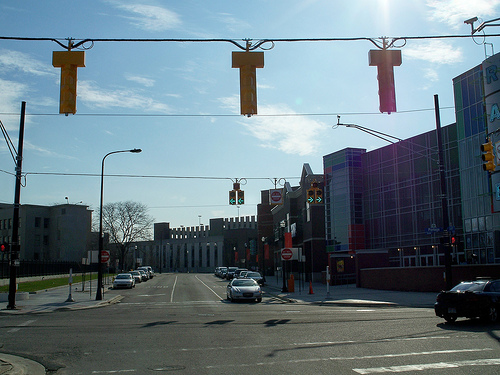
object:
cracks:
[17, 346, 62, 372]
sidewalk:
[2, 354, 40, 374]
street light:
[228, 182, 245, 206]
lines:
[169, 269, 179, 311]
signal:
[230, 197, 244, 205]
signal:
[308, 195, 322, 203]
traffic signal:
[305, 178, 326, 205]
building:
[227, 120, 459, 285]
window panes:
[362, 153, 444, 228]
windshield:
[455, 280, 485, 292]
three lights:
[35, 42, 437, 111]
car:
[112, 273, 134, 289]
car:
[130, 270, 142, 282]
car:
[134, 269, 147, 281]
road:
[121, 262, 240, 312]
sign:
[280, 246, 299, 262]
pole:
[277, 217, 296, 292]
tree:
[82, 203, 159, 272]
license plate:
[446, 306, 459, 315]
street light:
[367, 44, 403, 116]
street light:
[231, 44, 264, 117]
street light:
[50, 48, 84, 116]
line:
[0, 34, 498, 40]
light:
[477, 130, 496, 179]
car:
[433, 277, 497, 327]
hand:
[449, 235, 456, 246]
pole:
[433, 93, 453, 288]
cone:
[307, 278, 316, 295]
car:
[225, 277, 264, 304]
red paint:
[355, 270, 444, 292]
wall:
[348, 257, 460, 293]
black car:
[433, 276, 499, 325]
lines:
[193, 328, 440, 371]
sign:
[270, 188, 283, 205]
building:
[0, 193, 96, 271]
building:
[113, 214, 257, 273]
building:
[255, 184, 300, 267]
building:
[276, 161, 331, 285]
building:
[312, 49, 500, 290]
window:
[35, 215, 43, 228]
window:
[51, 245, 60, 259]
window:
[8, 219, 13, 231]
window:
[61, 208, 66, 215]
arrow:
[229, 198, 236, 205]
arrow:
[237, 198, 245, 205]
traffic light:
[228, 182, 244, 206]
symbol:
[336, 259, 345, 273]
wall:
[327, 251, 355, 283]